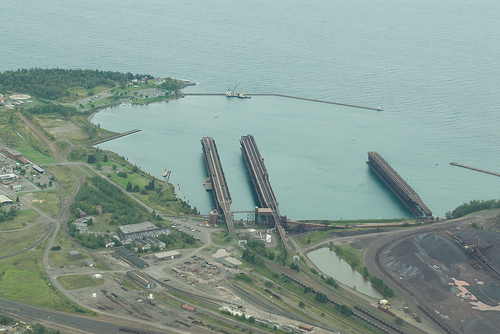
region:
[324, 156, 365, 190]
a body of water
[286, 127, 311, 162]
a body of water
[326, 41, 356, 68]
a body of water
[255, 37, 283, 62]
a body of water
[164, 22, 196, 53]
a body of water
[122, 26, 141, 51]
a body of water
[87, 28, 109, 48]
a body of water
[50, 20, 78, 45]
a body of water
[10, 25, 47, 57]
a body of water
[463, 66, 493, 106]
a body of water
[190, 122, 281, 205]
harbor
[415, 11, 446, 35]
white clouds in blue sky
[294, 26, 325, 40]
white clouds in blue sky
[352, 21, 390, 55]
white clouds in blue sky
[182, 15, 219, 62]
white clouds in blue sky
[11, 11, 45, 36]
white clouds in blue sky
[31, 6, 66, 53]
white clouds in blue sky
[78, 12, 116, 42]
white clouds in blue sky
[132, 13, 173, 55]
white clouds in blue sky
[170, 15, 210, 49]
white clouds in blue sky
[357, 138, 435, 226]
Lone pier on right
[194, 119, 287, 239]
Pair of piers.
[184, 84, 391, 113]
Barrier wall of canal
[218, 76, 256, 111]
Small boat in canal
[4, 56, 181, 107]
Cluster of trees at shoreline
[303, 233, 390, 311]
small inlet of water on right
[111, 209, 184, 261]
Factory building in front of piers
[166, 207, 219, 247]
Several cars parked by piers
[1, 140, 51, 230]
Cluster of buildings inland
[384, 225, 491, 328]
Huge pile of gravel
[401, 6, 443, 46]
white clouds in blue sky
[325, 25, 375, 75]
white clouds in blue sky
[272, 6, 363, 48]
white clouds in blue sky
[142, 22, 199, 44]
white clouds in blue sky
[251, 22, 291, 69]
white clouds in blue sky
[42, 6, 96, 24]
white clouds in blue sky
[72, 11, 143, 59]
white clouds in blue sky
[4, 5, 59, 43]
white clouds in blue sky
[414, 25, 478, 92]
white clouds in blue sky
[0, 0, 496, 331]
bird eyes view of city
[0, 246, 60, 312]
patch of grass between two roads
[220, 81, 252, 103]
boat next to a barrier in the water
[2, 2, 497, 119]
large body of water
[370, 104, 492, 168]
opening in to the ocean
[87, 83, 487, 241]
closed of fishing area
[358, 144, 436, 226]
docking extended into fishing area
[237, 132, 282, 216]
docking extended into fishing area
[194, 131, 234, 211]
docking extended into fishing area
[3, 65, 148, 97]
forest next to the shore